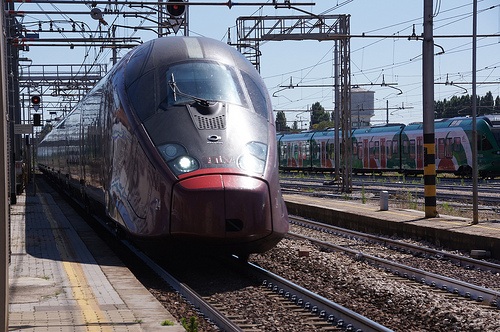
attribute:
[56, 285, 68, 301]
brick — tan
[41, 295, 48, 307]
brick — on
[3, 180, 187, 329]
sidewalk — brick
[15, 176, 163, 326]
sidewalk — tan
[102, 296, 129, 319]
brick — on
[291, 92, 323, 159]
ground — tan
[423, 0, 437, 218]
pole — striped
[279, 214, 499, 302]
train tracks — long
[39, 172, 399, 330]
train tracks — long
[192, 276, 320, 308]
track — on metal track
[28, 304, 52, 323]
brick — tan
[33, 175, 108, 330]
line — painted on platform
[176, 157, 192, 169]
headlight — off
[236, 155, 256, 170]
headlight — off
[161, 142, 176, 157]
headlight — off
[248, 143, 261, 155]
headlight — off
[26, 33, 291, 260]
train — metal, on metal track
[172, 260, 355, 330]
track — steel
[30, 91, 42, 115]
light — tall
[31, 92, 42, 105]
traffic light — tall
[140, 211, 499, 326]
pebbles — brown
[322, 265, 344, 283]
track — on metal track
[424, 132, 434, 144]
stripe — black 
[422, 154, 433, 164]
stripe — black 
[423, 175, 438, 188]
stripe — black 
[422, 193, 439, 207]
stripe — black 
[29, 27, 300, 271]
train — black, red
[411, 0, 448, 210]
pole — metal 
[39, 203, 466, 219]
platform — concrete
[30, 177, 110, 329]
stripe — yellow 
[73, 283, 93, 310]
paint — yellow